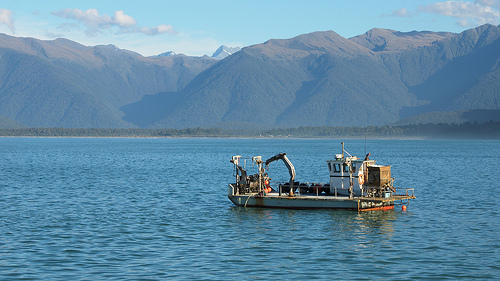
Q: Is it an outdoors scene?
A: Yes, it is outdoors.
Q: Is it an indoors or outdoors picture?
A: It is outdoors.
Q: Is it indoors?
A: No, it is outdoors.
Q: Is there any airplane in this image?
A: Yes, there is an airplane.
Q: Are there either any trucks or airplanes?
A: Yes, there is an airplane.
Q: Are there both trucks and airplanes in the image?
A: No, there is an airplane but no trucks.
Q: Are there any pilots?
A: No, there are no pilots.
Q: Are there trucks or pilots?
A: No, there are no pilots or trucks.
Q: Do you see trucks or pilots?
A: No, there are no pilots or trucks.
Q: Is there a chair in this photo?
A: No, there are no chairs.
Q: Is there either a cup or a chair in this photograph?
A: No, there are no chairs or cups.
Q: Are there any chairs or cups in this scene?
A: No, there are no chairs or cups.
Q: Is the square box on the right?
A: Yes, the box is on the right of the image.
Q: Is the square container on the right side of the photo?
A: Yes, the box is on the right of the image.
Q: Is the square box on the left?
A: No, the box is on the right of the image.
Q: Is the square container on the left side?
A: No, the box is on the right of the image.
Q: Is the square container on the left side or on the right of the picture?
A: The box is on the right of the image.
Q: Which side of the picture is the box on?
A: The box is on the right of the image.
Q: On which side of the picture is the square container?
A: The box is on the right of the image.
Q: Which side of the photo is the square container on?
A: The box is on the right of the image.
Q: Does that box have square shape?
A: Yes, the box is square.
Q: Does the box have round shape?
A: No, the box is square.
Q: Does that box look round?
A: No, the box is square.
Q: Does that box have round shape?
A: No, the box is square.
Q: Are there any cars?
A: No, there are no cars.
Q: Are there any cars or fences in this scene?
A: No, there are no cars or fences.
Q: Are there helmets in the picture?
A: No, there are no helmets.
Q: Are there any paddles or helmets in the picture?
A: No, there are no helmets or paddles.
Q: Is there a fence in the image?
A: No, there are no fences.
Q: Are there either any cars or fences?
A: No, there are no fences or cars.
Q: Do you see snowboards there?
A: No, there are no snowboards.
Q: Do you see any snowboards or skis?
A: No, there are no snowboards or skis.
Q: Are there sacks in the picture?
A: No, there are no sacks.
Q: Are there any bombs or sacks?
A: No, there are no sacks or bombs.